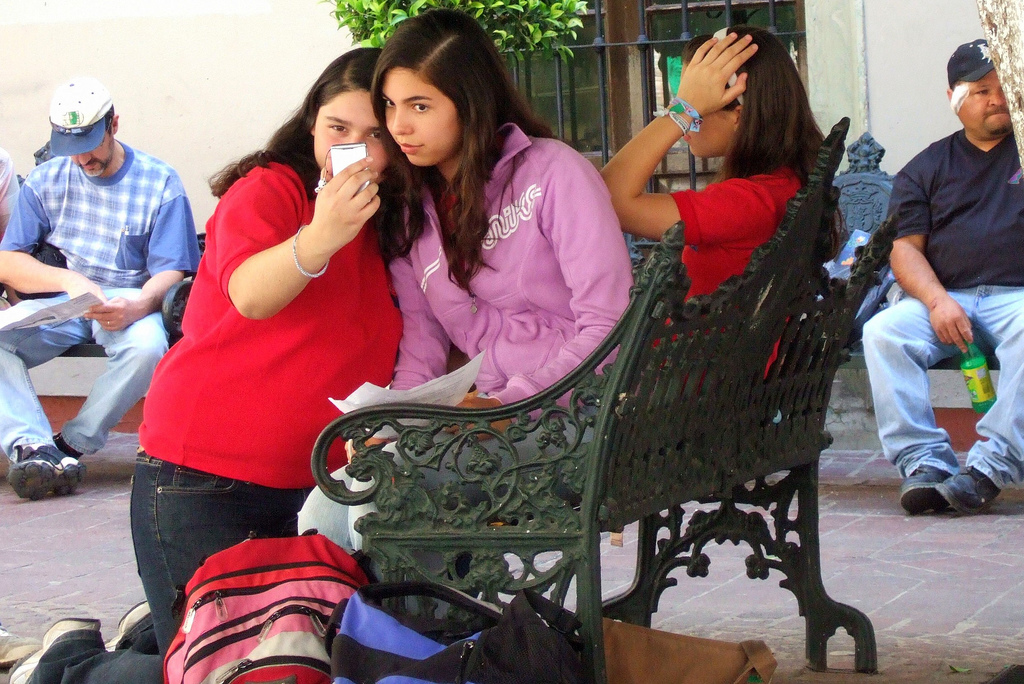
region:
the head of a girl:
[368, 22, 508, 223]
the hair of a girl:
[394, 19, 475, 95]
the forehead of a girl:
[389, 66, 435, 109]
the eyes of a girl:
[383, 89, 453, 127]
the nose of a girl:
[374, 107, 426, 145]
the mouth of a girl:
[392, 133, 430, 168]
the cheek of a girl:
[415, 107, 470, 168]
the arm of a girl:
[201, 203, 347, 328]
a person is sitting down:
[880, 41, 1020, 490]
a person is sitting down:
[588, 22, 827, 411]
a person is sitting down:
[4, 90, 195, 515]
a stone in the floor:
[891, 572, 983, 658]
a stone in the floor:
[866, 535, 1016, 578]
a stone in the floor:
[682, 570, 778, 638]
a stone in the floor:
[14, 521, 97, 582]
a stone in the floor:
[822, 472, 914, 508]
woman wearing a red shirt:
[141, 170, 413, 491]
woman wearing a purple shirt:
[382, 119, 624, 395]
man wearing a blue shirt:
[879, 123, 1022, 301]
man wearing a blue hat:
[935, 34, 1006, 104]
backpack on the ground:
[152, 515, 345, 678]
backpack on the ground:
[315, 565, 582, 677]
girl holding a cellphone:
[322, 145, 389, 240]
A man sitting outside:
[858, 32, 1021, 520]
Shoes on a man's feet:
[892, 456, 1000, 511]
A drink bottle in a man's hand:
[961, 339, 1000, 415]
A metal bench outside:
[304, 117, 883, 680]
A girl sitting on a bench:
[590, 19, 828, 374]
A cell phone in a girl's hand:
[323, 138, 384, 214]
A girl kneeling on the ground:
[8, 50, 413, 681]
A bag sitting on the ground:
[159, 531, 374, 681]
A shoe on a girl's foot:
[4, 612, 102, 682]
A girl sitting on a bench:
[362, 7, 629, 407]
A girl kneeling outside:
[7, 45, 404, 681]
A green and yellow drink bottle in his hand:
[953, 328, 998, 421]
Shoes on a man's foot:
[892, 451, 1001, 518]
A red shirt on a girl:
[131, 149, 400, 492]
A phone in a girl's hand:
[326, 132, 372, 190]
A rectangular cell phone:
[329, 143, 368, 197]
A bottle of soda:
[956, 332, 992, 413]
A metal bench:
[308, 114, 903, 681]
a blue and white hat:
[45, 74, 116, 157]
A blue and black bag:
[316, 576, 592, 682]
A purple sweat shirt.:
[371, 120, 635, 421]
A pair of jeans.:
[0, 288, 171, 460]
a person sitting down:
[618, 74, 891, 404]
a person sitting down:
[66, 85, 175, 364]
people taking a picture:
[132, 12, 889, 642]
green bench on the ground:
[275, 117, 1004, 639]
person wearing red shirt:
[126, 82, 477, 539]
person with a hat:
[17, 48, 305, 542]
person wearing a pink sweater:
[262, 40, 689, 515]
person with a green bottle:
[877, 35, 1017, 472]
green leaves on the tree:
[506, 1, 558, 62]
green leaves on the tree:
[523, 10, 558, 45]